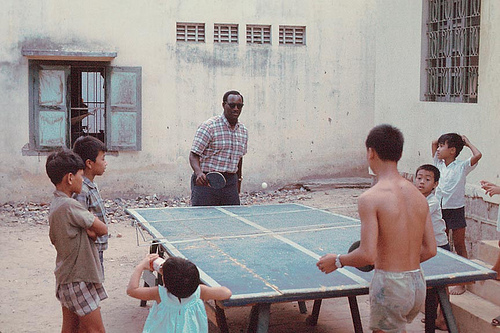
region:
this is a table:
[99, 161, 499, 331]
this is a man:
[185, 64, 278, 210]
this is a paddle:
[184, 164, 239, 194]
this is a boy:
[33, 143, 127, 331]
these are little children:
[18, 114, 495, 329]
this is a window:
[17, 30, 170, 183]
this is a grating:
[425, 30, 475, 100]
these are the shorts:
[33, 256, 110, 325]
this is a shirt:
[188, 113, 255, 178]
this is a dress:
[131, 268, 221, 332]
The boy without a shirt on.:
[322, 128, 434, 331]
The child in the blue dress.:
[141, 278, 216, 332]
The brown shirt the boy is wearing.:
[48, 196, 103, 276]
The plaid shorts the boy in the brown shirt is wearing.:
[50, 270, 110, 319]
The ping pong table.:
[128, 195, 498, 305]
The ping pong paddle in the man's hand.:
[202, 168, 227, 191]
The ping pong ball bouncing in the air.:
[260, 175, 270, 189]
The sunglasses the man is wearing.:
[228, 101, 243, 108]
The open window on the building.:
[62, 60, 106, 149]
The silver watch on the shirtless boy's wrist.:
[332, 252, 343, 267]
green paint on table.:
[274, 256, 301, 277]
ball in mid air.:
[256, 181, 273, 191]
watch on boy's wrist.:
[332, 253, 341, 272]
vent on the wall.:
[250, 25, 272, 41]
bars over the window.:
[424, 28, 476, 54]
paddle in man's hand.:
[210, 168, 225, 190]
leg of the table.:
[252, 307, 274, 332]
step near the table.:
[469, 298, 494, 320]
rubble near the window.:
[107, 190, 136, 210]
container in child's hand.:
[147, 252, 162, 275]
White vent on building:
[172, 14, 215, 49]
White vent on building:
[208, 20, 238, 48]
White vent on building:
[243, 17, 274, 49]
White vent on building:
[278, 20, 308, 51]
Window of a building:
[8, 35, 135, 171]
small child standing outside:
[31, 146, 116, 326]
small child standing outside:
[131, 245, 212, 330]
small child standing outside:
[328, 133, 409, 328]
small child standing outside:
[405, 155, 458, 271]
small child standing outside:
[430, 112, 478, 272]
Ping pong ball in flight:
[255, 178, 273, 194]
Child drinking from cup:
[126, 252, 232, 329]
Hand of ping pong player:
[313, 248, 338, 275]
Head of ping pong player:
[361, 120, 404, 178]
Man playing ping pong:
[190, 90, 248, 200]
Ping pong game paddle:
[196, 170, 233, 205]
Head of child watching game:
[39, 147, 88, 197]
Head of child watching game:
[68, 136, 106, 177]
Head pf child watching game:
[412, 164, 440, 196]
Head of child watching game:
[433, 131, 464, 167]